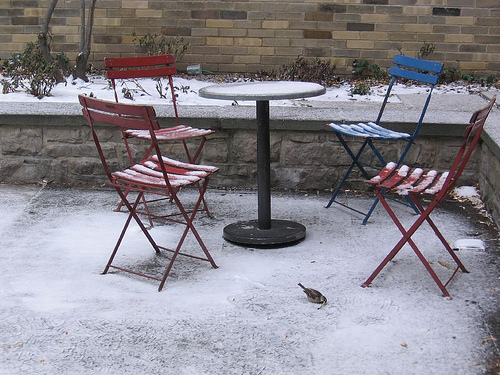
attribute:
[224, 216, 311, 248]
base — round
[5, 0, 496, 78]
building — brick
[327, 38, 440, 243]
chair — red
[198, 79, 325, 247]
table — round, black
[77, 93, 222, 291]
chair — red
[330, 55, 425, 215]
chair — blue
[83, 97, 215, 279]
chair — red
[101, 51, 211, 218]
chair — red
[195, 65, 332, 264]
table — black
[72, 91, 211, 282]
chair — red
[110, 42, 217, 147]
chair — red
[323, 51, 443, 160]
chair — blue